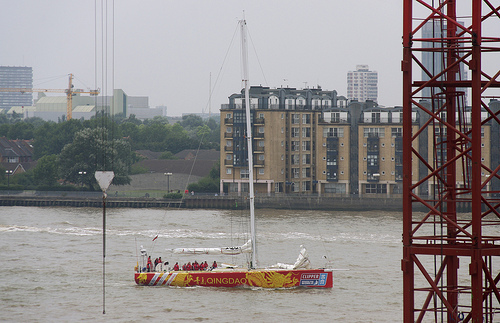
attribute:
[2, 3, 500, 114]
sky — blue, gray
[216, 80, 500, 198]
building — brown, large, tan, black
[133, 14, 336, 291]
boat — long, red, yellow, colorful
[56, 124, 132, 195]
tree — green, large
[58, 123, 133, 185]
leaves — green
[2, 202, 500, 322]
water — calm, gray, brown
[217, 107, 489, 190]
wall — brown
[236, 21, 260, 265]
pole — long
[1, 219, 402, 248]
waves — small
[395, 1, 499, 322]
post — red, tall, metal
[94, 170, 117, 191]
sign — metal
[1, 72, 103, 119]
crane — bright yellow, yellow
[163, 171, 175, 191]
light — small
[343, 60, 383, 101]
building — tall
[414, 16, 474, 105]
building — tall